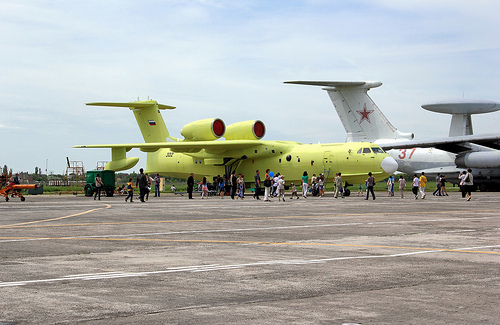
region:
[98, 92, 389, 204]
this is a yellow plane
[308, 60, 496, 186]
this is a white plane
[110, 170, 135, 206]
this is a person at the airport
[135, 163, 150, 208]
this is a person at the airport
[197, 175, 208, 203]
this is a person at the airport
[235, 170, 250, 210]
this is a person at the airport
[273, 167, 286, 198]
this is a person at the airport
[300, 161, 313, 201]
this is a person at the airport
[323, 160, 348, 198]
this is a person at the airport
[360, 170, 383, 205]
this is a person at the airport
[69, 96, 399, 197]
the big yellow plane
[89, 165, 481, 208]
the people on the tarmac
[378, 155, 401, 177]
the nose of the plane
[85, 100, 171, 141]
the tail on the plane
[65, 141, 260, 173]
the wing of the plane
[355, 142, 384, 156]
the windows on the yellow plane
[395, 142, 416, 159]
the number 37 on the plane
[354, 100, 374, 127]
the star on the plane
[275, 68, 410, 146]
the tail of the white plane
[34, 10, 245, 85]
the clouds in the sky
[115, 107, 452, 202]
yellow airplane on runway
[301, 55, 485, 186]
white plane next to yellow plane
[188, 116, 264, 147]
large engines on yellow plane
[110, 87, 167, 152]
large tail on yellow plane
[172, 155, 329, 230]
people walking around yellow plane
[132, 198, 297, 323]
tarmac is light grey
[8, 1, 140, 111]
sky is blue and hazy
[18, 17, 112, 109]
few clouds in sky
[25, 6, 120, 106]
clouds are white and thin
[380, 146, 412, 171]
37 on white plane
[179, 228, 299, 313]
the ground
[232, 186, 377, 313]
the ground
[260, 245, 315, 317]
the ground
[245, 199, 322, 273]
the ground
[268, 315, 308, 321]
the ground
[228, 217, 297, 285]
the ground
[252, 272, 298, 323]
the ground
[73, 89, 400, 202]
a yellow cargo plane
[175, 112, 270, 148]
red turbine engines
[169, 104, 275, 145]
the engines on the wing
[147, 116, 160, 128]
a flag on the tail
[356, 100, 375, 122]
a star on the tail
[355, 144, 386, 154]
the cockpit window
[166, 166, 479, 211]
the crowd looks at the planes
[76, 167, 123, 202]
a green standing trailer.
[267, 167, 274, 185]
the person has a blue ballon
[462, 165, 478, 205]
the women with her purse on her shoulder